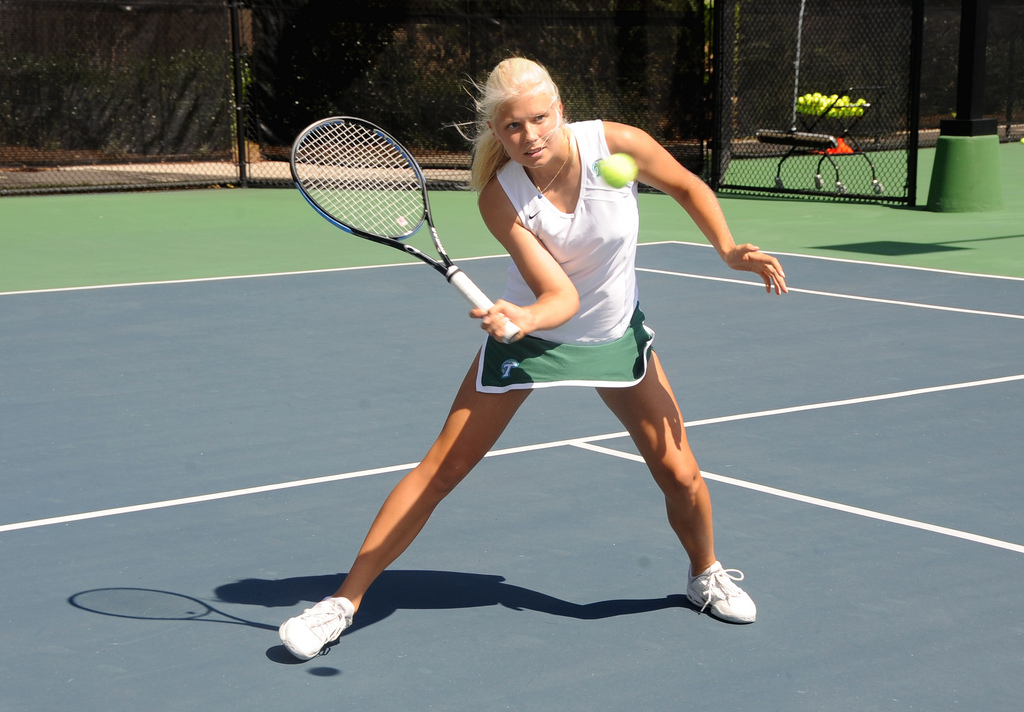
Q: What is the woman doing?
A: Playing tennis.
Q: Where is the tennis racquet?
A: Players right hand.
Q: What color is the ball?
A: Yellow.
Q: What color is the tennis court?
A: Blue.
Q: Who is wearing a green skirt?
A: Tennis player.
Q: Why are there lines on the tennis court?
A: Mark boundaries.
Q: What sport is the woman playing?
A: Tennis.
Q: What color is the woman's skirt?
A: Green.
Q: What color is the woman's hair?
A: Blonde.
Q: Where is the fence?
A: Around the tennis court.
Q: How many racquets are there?
A: 1.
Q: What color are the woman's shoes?
A: White.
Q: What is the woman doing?
A: The woman is playing tennis.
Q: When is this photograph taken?
A: This is taken during the day.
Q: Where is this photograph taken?
A: On a tennis court.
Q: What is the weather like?
A: Sunny.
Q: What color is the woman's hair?
A: Blonde.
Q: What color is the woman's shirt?
A: White.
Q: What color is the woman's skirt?
A: Green with white trim.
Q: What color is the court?
A: Blue and green.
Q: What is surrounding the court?
A: A fence.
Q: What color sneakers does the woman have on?
A: White.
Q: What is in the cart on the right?
A: Tennis balls.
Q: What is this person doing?
A: Playing tennis.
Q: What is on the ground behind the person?
A: Her shadow.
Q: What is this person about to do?
A: Hit the tennis ball.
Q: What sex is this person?
A: Female.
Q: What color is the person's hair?
A: Blonde.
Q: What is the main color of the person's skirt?
A: Green.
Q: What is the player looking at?
A: The ball.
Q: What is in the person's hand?
A: Tennis racket.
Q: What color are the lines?
A: White.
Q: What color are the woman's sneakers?
A: White.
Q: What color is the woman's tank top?
A: White.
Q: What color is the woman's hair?
A: Blonde.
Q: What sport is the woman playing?
A: Tennis.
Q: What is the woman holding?
A: A tennis racket.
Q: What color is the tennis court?
A: Blue and green.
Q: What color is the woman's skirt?
A: Green.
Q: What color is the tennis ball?
A: Yellow.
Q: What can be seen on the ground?
A: A shadow.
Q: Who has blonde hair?
A: Tennis player.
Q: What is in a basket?
A: Tennis balls.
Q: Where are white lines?
A: On tennis court.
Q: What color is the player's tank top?
A: White.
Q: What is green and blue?
A: Court.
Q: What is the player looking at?
A: Tennis ball.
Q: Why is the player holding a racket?
A: To hit the ball.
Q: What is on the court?
A: Shadows.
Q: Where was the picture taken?
A: At a tennis court.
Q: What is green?
A: Player's skirt.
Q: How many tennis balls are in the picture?
A: 1.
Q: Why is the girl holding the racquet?
A: To hit the ball.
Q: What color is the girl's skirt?
A: Green.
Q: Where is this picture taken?
A: Tennis court.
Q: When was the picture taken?
A: During tennis game.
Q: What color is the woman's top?
A: White.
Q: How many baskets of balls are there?
A: 1.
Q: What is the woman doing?
A: Playing tennis.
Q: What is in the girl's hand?
A: Tennis racket.